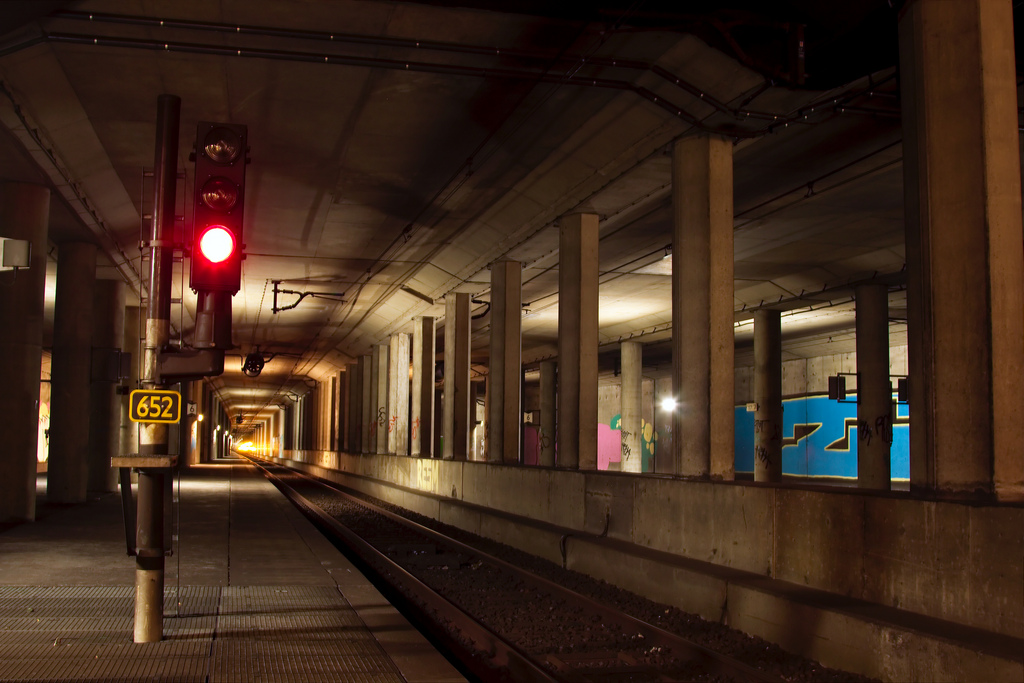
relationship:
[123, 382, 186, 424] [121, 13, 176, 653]
sign on pole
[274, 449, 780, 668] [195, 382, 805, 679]
rail for train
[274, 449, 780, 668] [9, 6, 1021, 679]
rail in train station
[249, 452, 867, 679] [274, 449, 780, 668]
dirt covering rail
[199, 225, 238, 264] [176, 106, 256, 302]
light lit up on traffic light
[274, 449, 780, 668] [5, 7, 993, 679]
rail placed inside tunnel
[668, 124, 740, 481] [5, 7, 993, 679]
pole holding up tunnel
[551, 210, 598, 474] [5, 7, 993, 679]
pole holding up tunnel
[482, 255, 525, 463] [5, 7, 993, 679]
pole holding up tunnel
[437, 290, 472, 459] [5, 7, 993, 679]
support column holding up tunnel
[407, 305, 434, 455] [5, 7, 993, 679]
support column holding up tunnel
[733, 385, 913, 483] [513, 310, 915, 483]
art painted on wall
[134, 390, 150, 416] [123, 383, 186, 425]
number painted on sign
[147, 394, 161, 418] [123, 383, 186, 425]
number painted on sign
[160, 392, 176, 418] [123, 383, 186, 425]
number painted on sign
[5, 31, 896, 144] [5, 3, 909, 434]
conduit running across ceiling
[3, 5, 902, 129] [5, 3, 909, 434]
conduit running across ceiling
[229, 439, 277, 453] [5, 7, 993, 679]
light coming into tunnel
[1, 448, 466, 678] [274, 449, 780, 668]
platform built alongside rail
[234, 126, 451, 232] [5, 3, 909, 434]
shadow casted on ceiling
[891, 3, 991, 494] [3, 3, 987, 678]
pole supporting building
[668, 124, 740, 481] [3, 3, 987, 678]
pole supporting building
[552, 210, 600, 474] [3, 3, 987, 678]
pole supporting building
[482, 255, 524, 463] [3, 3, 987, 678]
pole supporting building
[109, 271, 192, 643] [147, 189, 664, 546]
pole on building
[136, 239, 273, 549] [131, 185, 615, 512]
pole on building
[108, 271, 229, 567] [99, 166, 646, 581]
pole on building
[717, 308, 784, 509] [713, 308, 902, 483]
pole on building